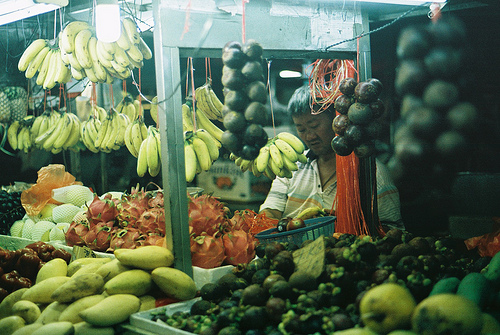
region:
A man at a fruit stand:
[183, 55, 360, 282]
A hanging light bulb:
[21, 1, 153, 44]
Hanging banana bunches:
[8, 84, 219, 160]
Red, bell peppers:
[0, 224, 51, 293]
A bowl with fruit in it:
[248, 209, 339, 252]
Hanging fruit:
[392, 1, 462, 188]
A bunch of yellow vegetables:
[17, 240, 168, 333]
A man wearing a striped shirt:
[271, 82, 335, 244]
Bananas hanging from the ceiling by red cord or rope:
[184, 53, 214, 183]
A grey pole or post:
[160, 1, 187, 246]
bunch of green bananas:
[241, 134, 312, 189]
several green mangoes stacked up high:
[35, 248, 182, 315]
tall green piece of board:
[145, 0, 210, 280]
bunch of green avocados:
[207, 266, 297, 310]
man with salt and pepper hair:
[288, 88, 345, 159]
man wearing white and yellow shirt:
[265, 149, 356, 213]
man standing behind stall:
[245, 79, 376, 239]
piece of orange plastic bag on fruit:
[15, 160, 85, 209]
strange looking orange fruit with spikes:
[71, 194, 250, 262]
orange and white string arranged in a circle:
[305, 46, 381, 109]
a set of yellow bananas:
[15, 19, 154, 92]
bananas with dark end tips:
[18, 15, 153, 89]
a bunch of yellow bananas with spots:
[8, 93, 165, 179]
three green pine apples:
[2, 84, 31, 122]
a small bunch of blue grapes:
[331, 77, 393, 158]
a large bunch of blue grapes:
[222, 42, 276, 160]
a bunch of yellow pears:
[335, 282, 498, 334]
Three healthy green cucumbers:
[426, 251, 498, 311]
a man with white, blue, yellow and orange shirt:
[257, 80, 407, 233]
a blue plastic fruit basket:
[254, 214, 341, 260]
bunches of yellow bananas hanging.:
[6, 20, 308, 176]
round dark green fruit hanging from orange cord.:
[222, 20, 475, 196]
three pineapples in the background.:
[0, 81, 32, 124]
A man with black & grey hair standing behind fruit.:
[257, 83, 348, 222]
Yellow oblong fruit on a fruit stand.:
[1, 246, 198, 332]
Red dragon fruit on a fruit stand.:
[66, 188, 281, 266]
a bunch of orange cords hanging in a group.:
[307, 42, 367, 239]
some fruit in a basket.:
[255, 215, 339, 249]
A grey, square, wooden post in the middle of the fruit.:
[150, 1, 201, 280]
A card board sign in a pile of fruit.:
[272, 236, 339, 282]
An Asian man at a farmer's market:
[266, 82, 358, 233]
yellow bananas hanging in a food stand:
[0, 13, 309, 176]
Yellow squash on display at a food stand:
[1, 246, 233, 333]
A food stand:
[0, 1, 497, 333]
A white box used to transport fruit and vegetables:
[192, 150, 277, 208]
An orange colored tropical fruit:
[74, 187, 281, 270]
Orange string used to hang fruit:
[307, 54, 396, 249]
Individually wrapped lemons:
[11, 167, 99, 250]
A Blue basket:
[251, 210, 346, 257]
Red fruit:
[1, 236, 71, 296]